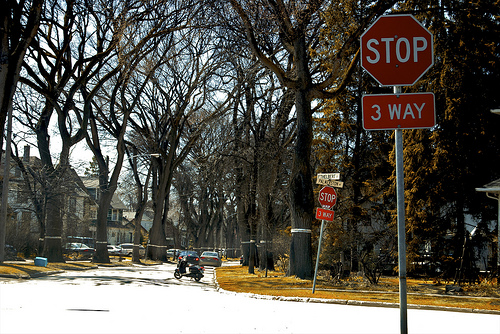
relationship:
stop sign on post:
[358, 14, 437, 88] [391, 88, 408, 333]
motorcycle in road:
[173, 254, 207, 282] [8, 255, 497, 326]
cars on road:
[177, 242, 225, 266] [8, 255, 497, 326]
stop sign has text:
[358, 14, 437, 88] [364, 34, 427, 66]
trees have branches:
[5, 3, 316, 280] [79, 18, 239, 128]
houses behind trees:
[3, 145, 176, 250] [5, 3, 316, 280]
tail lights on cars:
[201, 257, 224, 264] [177, 242, 225, 266]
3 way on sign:
[367, 98, 434, 124] [359, 91, 440, 135]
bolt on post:
[393, 91, 405, 104] [391, 88, 408, 333]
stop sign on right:
[358, 14, 437, 88] [334, 8, 490, 333]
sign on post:
[359, 91, 440, 135] [391, 88, 408, 333]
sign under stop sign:
[359, 91, 440, 135] [358, 14, 437, 88]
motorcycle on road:
[173, 254, 207, 282] [8, 255, 497, 326]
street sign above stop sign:
[318, 167, 345, 188] [318, 184, 344, 208]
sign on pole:
[313, 186, 342, 229] [306, 220, 333, 302]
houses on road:
[3, 145, 176, 250] [0, 259, 500, 334]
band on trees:
[287, 222, 308, 237] [5, 3, 316, 280]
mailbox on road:
[114, 247, 127, 265] [8, 255, 497, 326]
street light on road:
[92, 146, 166, 261] [8, 255, 497, 326]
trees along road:
[5, 3, 316, 280] [8, 255, 497, 326]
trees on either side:
[5, 3, 316, 280] [36, 234, 300, 308]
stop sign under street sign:
[318, 184, 344, 208] [318, 167, 345, 188]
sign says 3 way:
[359, 91, 440, 135] [367, 98, 434, 124]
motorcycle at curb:
[173, 254, 207, 282] [209, 270, 497, 316]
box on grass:
[32, 255, 52, 267] [10, 252, 73, 276]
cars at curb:
[177, 242, 225, 266] [209, 270, 497, 316]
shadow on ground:
[56, 265, 168, 292] [33, 233, 224, 323]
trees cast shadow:
[5, 3, 316, 280] [56, 265, 168, 292]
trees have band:
[5, 3, 316, 280] [287, 222, 308, 237]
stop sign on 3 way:
[358, 14, 437, 88] [367, 98, 434, 124]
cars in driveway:
[177, 242, 225, 266] [58, 236, 221, 258]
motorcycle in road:
[173, 254, 207, 282] [0, 259, 500, 334]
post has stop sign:
[391, 88, 408, 333] [318, 184, 344, 208]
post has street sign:
[391, 88, 408, 333] [318, 167, 345, 188]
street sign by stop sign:
[318, 167, 345, 188] [318, 184, 344, 208]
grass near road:
[10, 252, 73, 276] [0, 259, 500, 334]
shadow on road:
[56, 265, 168, 292] [8, 255, 497, 326]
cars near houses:
[60, 244, 183, 259] [3, 145, 176, 250]